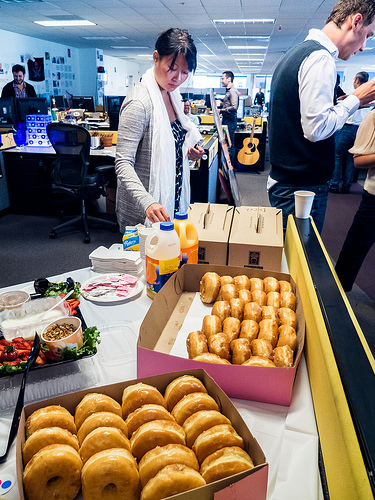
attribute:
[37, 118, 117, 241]
chair — black, swivel, office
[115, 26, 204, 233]
woman — dark haired, black haired, Asian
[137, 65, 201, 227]
scarf — white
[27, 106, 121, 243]
desk chair — black, silver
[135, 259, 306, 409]
box — pink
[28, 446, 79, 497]
doughnuts — golden brown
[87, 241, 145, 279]
napkins — white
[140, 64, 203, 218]
scarf — long, white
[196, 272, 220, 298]
doughnuts — golden brown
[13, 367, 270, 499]
box — pink, cardboard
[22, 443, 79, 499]
doughnut — golden brown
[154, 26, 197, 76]
hair — black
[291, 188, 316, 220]
cup — small, white, disposable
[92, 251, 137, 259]
napkin — white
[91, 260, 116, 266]
napkin — white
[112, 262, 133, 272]
napkin — white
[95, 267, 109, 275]
napkin — white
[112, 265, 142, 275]
napkin — white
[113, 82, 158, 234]
sweater — grey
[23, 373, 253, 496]
donuts — glazed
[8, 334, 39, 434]
black — large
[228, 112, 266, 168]
guitar — long, brown, acoustic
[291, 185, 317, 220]
cup — white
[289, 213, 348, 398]
rail — black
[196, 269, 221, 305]
doughnuts — golden brown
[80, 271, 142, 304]
plate — white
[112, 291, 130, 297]
sugar packet — white, pink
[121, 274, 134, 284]
sugar packet — white, pink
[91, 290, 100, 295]
sugar packet — white, pink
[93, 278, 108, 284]
sugar packet — white, pink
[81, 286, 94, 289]
sugar packet — white, pink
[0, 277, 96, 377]
tray — black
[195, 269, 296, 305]
doughnuts — golden brown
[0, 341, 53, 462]
tongs — long, black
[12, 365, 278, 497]
doughnuts — golden brown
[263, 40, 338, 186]
vest — black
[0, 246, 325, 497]
tablecloth — with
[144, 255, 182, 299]
juice — orange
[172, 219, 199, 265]
juice — orange